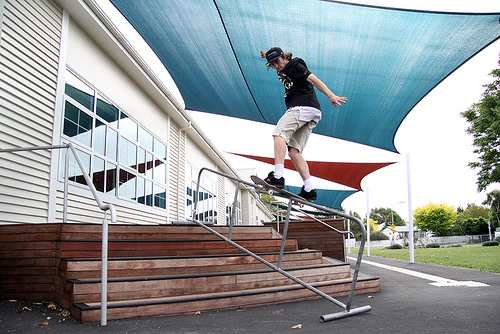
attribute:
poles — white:
[352, 143, 426, 268]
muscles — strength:
[268, 130, 323, 184]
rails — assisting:
[211, 179, 398, 309]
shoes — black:
[254, 165, 325, 199]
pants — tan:
[264, 105, 325, 152]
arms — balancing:
[245, 50, 382, 115]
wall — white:
[51, 31, 177, 136]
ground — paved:
[107, 293, 499, 329]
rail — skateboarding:
[170, 165, 372, 322]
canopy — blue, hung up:
[109, 0, 497, 152]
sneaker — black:
[262, 167, 287, 190]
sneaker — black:
[296, 182, 323, 200]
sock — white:
[266, 158, 286, 179]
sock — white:
[298, 177, 318, 193]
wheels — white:
[259, 182, 309, 217]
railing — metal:
[186, 156, 376, 316]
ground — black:
[355, 277, 484, 332]